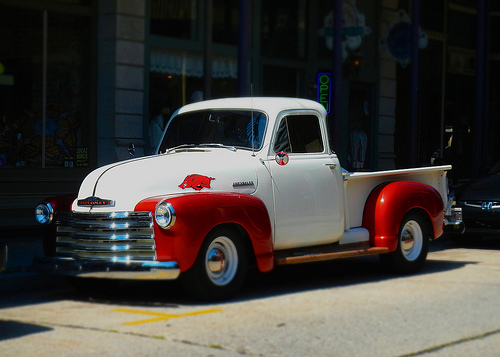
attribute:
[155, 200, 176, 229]
light — silver 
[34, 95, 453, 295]
truck — red and white, old 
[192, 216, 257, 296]
tire — black and white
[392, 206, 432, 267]
tire — black and white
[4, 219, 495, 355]
pavement — gray 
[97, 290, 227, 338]
guidlines — yellow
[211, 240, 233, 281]
hubcaps — silver, white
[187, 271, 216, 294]
tires — black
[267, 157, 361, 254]
door — white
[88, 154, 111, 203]
stripe — metal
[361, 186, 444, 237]
metal — red, curved